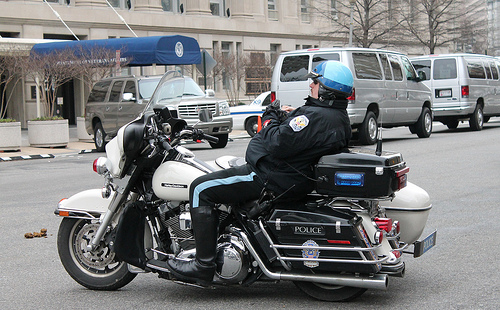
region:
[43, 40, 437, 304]
The man is sitting on a motorcycle.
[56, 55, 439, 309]
The man is leaning back.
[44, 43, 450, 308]
The man is wearing a helmet.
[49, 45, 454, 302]
The man is wearing a uniform.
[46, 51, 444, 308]
The motorcycle is white.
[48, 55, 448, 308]
The motorcycle is police issue.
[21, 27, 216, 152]
The awning is blue and white.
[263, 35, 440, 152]
The van is silver.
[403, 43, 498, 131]
The van is silver.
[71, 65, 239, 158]
The SUV is silver.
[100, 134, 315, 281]
this is a motorcycle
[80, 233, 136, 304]
this is a wheel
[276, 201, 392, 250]
this says police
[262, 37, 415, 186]
this is a helmet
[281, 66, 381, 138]
the helmet is blue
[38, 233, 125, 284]
the tires are black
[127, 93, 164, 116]
this is a window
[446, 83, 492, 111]
this is a red light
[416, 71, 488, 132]
this is a plate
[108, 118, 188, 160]
this is a handle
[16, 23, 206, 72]
blue awning over doorway of building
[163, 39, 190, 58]
design on front of building awning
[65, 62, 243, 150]
parked silver vehicle by building door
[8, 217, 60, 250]
trash laying on road pavement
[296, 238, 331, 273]
police logo on side of motorcycle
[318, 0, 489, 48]
trees branches with no leaves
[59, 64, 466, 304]
cop sitting on motorcycle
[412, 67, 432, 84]
black side mirror on van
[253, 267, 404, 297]
silver metal motorcycle exhaust pipe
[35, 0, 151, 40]
white metal awning support poles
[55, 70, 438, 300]
Motorcycle on the road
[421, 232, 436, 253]
Licence plate on the motorcycle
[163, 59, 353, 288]
Man sitting on the motorcycle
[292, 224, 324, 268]
Police sign on the motorcycle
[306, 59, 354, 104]
Helmet on the man's head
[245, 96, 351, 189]
Black jacket on the man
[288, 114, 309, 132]
Police badge on the man's jacket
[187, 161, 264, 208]
Pants on the man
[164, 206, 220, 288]
Boot on the man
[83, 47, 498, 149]
Cars on the road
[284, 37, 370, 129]
man wearing blue helmet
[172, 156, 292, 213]
police officer wearing black and blue pants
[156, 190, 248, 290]
police officer wearing leather boots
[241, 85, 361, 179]
police officer wearing black jacket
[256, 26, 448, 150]
silver van on road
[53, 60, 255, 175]
silver suv parked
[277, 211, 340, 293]
police sign on motorcycle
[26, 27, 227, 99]
blue tent over entrance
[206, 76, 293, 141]
white and blue police car parked